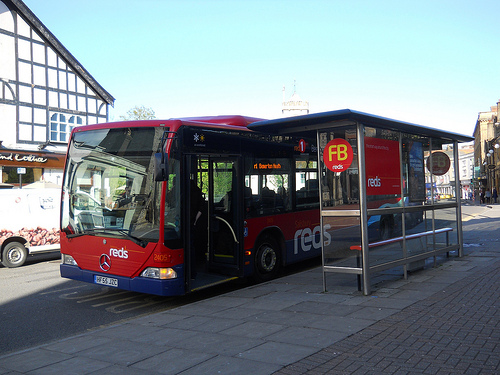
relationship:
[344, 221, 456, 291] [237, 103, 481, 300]
seat in bus stop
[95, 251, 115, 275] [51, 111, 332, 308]
symbol on front of bus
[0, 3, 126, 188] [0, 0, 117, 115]
building has top half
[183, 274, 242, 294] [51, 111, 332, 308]
edge on side of bus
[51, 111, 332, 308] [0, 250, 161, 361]
bus on top of street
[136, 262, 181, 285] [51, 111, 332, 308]
headlight on front of bus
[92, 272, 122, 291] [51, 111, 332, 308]
license plate on front of bus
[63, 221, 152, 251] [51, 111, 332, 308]
wiper on front of bus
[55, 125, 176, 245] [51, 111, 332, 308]
windshield on front of bus